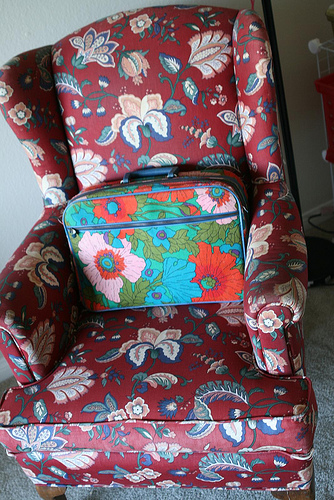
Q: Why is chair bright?
A: Sun.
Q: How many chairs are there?
A: One.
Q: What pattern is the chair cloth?
A: Flowers.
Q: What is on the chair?
A: Tote.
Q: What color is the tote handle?
A: Blue.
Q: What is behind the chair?
A: Wall.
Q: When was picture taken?
A: Daytime.